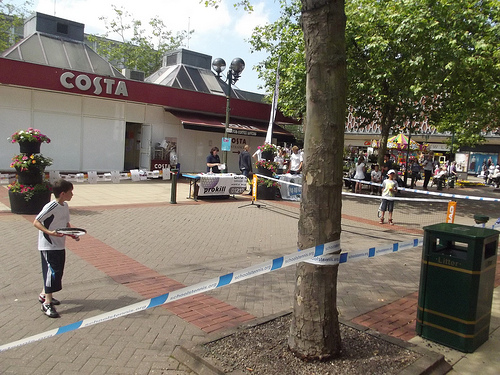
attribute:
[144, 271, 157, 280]
brick — paved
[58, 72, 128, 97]
sign — White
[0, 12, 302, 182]
building — White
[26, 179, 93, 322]
boy — little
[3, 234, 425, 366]
tape — white 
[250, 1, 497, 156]
leaves — green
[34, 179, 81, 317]
boy — Walking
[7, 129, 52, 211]
tiered plant — Green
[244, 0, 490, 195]
tree — Green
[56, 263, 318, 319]
tape — white 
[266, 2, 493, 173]
tree — large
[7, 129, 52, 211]
planter — tiered, outdoor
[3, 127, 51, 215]
flower pot — Large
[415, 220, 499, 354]
trash can — green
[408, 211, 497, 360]
trashcan — green 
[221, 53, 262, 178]
pole — metal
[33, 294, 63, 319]
shoes — Worn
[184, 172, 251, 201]
table — blue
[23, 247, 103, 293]
shorts — blue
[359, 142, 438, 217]
boy — small